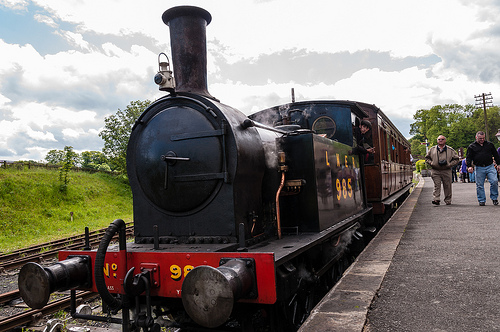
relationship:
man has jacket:
[424, 135, 460, 205] [424, 144, 461, 170]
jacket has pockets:
[424, 144, 461, 170] [432, 160, 449, 169]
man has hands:
[424, 135, 460, 205] [431, 162, 452, 168]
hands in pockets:
[431, 162, 452, 168] [432, 160, 449, 169]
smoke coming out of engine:
[236, 90, 330, 169] [18, 5, 369, 331]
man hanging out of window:
[353, 118, 377, 154] [356, 118, 363, 146]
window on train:
[356, 118, 363, 146] [18, 5, 415, 332]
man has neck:
[424, 135, 460, 205] [438, 143, 446, 147]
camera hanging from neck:
[437, 146, 448, 167] [438, 143, 446, 147]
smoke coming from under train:
[322, 228, 357, 258] [18, 5, 415, 332]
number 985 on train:
[334, 178, 353, 201] [18, 5, 415, 332]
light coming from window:
[392, 145, 395, 150] [391, 136, 396, 162]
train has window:
[18, 5, 415, 332] [391, 136, 396, 162]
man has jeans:
[467, 131, 499, 207] [476, 165, 499, 203]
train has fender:
[18, 5, 415, 332] [59, 249, 277, 304]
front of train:
[127, 94, 237, 242] [18, 5, 415, 332]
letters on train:
[326, 151, 357, 169] [18, 5, 415, 332]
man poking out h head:
[353, 118, 377, 154] [359, 119, 372, 134]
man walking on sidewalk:
[424, 135, 460, 205] [296, 175, 500, 331]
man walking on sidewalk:
[467, 131, 499, 207] [296, 175, 500, 331]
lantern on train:
[154, 52, 175, 90] [18, 5, 415, 332]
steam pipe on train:
[275, 151, 285, 237] [18, 5, 415, 332]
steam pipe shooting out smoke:
[275, 151, 285, 237] [236, 90, 330, 169]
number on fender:
[169, 265, 194, 279] [59, 249, 277, 304]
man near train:
[424, 135, 460, 205] [18, 5, 415, 332]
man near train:
[467, 131, 499, 207] [18, 5, 415, 332]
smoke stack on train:
[161, 5, 220, 104] [18, 5, 415, 332]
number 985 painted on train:
[334, 178, 353, 201] [18, 5, 415, 332]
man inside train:
[353, 118, 377, 154] [18, 5, 415, 332]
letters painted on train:
[326, 151, 357, 169] [18, 5, 415, 332]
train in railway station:
[18, 5, 415, 332] [1, 176, 498, 330]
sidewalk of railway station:
[296, 175, 500, 331] [1, 176, 498, 330]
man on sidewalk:
[424, 135, 460, 205] [296, 175, 500, 331]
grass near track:
[0, 164, 133, 258] [0, 220, 293, 331]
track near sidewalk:
[0, 220, 293, 331] [296, 175, 500, 331]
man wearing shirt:
[467, 131, 499, 207] [467, 141, 499, 167]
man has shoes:
[424, 135, 460, 205] [433, 199, 453, 206]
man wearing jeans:
[467, 131, 499, 207] [476, 165, 499, 203]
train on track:
[18, 5, 415, 332] [0, 220, 293, 331]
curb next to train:
[295, 174, 425, 331] [18, 5, 415, 332]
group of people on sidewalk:
[452, 156, 477, 182] [296, 175, 500, 331]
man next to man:
[424, 135, 460, 205] [467, 131, 499, 207]